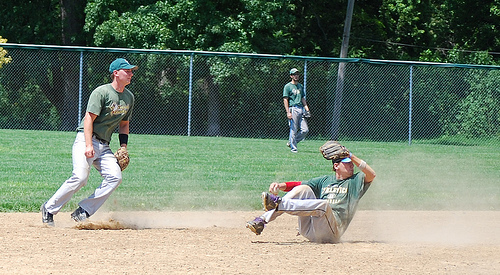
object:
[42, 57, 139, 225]
man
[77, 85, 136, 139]
t shirt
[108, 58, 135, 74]
cap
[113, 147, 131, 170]
glove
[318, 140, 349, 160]
glove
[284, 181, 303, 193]
sleeve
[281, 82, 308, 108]
shirt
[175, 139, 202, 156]
grass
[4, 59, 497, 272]
baseball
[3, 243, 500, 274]
ground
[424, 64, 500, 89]
fence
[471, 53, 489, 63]
bush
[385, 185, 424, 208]
cloud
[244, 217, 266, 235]
cleats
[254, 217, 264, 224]
laces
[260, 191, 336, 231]
legs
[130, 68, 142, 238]
forward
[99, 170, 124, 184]
knees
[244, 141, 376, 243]
action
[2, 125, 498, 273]
baseball field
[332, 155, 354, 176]
head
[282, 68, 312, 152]
man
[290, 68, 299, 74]
cap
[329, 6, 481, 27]
up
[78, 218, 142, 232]
dust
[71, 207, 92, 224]
shoe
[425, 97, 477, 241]
same direction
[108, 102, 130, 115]
writing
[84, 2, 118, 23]
these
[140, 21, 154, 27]
leaves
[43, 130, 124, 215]
pants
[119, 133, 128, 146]
band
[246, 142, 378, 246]
man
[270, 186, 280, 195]
ball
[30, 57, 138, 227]
stop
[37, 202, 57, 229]
feet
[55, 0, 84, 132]
tree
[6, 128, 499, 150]
edge of outfield